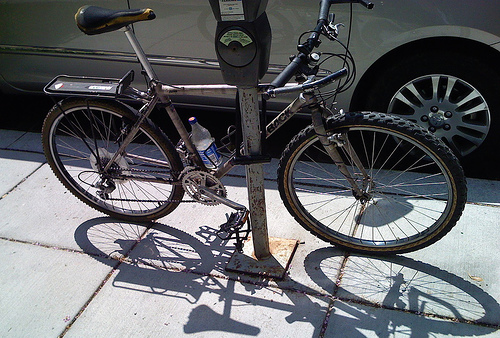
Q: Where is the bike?
A: On the pole.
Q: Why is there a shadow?
A: It is sunny.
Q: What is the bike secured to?
A: Parking meter.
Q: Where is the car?
A: Behind the bike.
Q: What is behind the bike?
A: Car.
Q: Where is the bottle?
A: On the bicycle.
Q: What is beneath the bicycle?
A: Sidewalk.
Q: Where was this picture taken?
A: Side of a street.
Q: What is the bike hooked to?
A: A meter.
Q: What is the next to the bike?
A: A car wheel.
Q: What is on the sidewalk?
A: Bike.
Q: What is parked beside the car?
A: A bike.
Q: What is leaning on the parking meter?
A: A bike.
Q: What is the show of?
A: A bike.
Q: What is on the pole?
A: A meter.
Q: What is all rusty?
A: A pole.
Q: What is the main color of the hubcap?
A: Gray.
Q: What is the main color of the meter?
A: Black.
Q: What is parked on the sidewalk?
A: A bike.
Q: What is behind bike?
A: A car.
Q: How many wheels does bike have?
A: Two.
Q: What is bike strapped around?
A: A parking meter.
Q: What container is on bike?
A: A water bottle.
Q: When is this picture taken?
A: Daytime.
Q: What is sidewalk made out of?
A: Concrete.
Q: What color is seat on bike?
A: Black.